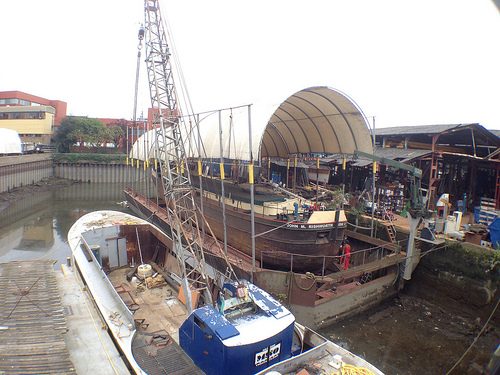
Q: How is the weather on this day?
A: It is cloudy.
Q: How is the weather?
A: It is cloudy.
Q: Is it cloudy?
A: Yes, it is cloudy.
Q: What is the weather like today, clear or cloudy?
A: It is cloudy.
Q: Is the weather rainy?
A: No, it is cloudy.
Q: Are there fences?
A: No, there are no fences.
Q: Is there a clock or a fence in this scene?
A: No, there are no fences or clocks.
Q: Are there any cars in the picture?
A: No, there are no cars.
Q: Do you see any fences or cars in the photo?
A: No, there are no cars or fences.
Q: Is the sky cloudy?
A: Yes, the sky is cloudy.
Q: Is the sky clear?
A: No, the sky is cloudy.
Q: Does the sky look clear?
A: No, the sky is cloudy.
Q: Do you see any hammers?
A: No, there are no hammers.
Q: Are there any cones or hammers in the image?
A: No, there are no hammers or cones.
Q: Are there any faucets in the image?
A: No, there are no faucets.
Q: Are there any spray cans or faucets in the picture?
A: No, there are no faucets or spray cans.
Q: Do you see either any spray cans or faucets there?
A: No, there are no faucets or spray cans.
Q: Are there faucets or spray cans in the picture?
A: No, there are no faucets or spray cans.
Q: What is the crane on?
A: The crane is on the boat.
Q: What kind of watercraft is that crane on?
A: The crane is on the boat.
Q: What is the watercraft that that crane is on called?
A: The watercraft is a boat.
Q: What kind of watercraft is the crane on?
A: The crane is on the boat.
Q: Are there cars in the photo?
A: No, there are no cars.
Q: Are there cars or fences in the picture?
A: No, there are no cars or fences.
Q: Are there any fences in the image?
A: No, there are no fences.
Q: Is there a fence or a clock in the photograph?
A: No, there are no fences or clocks.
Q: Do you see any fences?
A: No, there are no fences.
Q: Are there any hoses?
A: No, there are no hoses.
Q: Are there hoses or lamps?
A: No, there are no hoses or lamps.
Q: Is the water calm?
A: Yes, the water is calm.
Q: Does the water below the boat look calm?
A: Yes, the water is calm.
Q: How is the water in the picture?
A: The water is calm.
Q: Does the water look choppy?
A: No, the water is calm.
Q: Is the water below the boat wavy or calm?
A: The water is calm.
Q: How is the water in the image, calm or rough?
A: The water is calm.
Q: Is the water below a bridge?
A: No, the water is below the boat.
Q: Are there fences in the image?
A: No, there are no fences.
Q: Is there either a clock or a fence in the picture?
A: No, there are no fences or clocks.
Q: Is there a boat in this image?
A: Yes, there is a boat.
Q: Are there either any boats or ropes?
A: Yes, there is a boat.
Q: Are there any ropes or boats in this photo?
A: Yes, there is a boat.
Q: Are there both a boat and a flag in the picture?
A: No, there is a boat but no flags.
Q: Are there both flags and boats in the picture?
A: No, there is a boat but no flags.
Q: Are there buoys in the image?
A: No, there are no buoys.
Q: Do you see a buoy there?
A: No, there are no buoys.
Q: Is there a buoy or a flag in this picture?
A: No, there are no buoys or flags.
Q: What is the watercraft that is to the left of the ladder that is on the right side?
A: The watercraft is a boat.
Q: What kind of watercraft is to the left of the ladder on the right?
A: The watercraft is a boat.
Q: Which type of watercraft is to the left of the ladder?
A: The watercraft is a boat.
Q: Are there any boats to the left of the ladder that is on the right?
A: Yes, there is a boat to the left of the ladder.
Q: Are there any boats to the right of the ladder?
A: No, the boat is to the left of the ladder.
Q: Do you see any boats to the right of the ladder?
A: No, the boat is to the left of the ladder.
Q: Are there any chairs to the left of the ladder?
A: No, there is a boat to the left of the ladder.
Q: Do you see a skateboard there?
A: No, there are no skateboards.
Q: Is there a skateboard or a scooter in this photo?
A: No, there are no skateboards or scooters.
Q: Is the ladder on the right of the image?
A: Yes, the ladder is on the right of the image.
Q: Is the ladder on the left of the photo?
A: No, the ladder is on the right of the image.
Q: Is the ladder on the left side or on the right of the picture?
A: The ladder is on the right of the image.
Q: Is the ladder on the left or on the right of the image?
A: The ladder is on the right of the image.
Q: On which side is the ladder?
A: The ladder is on the right of the image.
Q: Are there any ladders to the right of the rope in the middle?
A: Yes, there is a ladder to the right of the rope.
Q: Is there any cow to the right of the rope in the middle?
A: No, there is a ladder to the right of the rope.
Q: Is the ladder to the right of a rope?
A: Yes, the ladder is to the right of a rope.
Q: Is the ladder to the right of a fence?
A: No, the ladder is to the right of a rope.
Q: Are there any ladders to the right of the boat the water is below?
A: Yes, there is a ladder to the right of the boat.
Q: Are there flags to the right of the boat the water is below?
A: No, there is a ladder to the right of the boat.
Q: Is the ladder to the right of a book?
A: No, the ladder is to the right of a boat.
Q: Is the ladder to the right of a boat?
A: Yes, the ladder is to the right of a boat.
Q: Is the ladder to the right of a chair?
A: No, the ladder is to the right of a boat.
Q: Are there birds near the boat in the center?
A: No, there is a ladder near the boat.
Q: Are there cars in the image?
A: No, there are no cars.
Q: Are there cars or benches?
A: No, there are no cars or benches.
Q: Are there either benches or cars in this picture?
A: No, there are no cars or benches.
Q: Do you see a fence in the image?
A: No, there are no fences.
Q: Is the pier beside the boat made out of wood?
A: Yes, the dock is made of wood.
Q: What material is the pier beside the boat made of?
A: The pier is made of wood.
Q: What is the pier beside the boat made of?
A: The pier is made of wood.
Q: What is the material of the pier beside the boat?
A: The pier is made of wood.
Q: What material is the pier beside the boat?
A: The pier is made of wood.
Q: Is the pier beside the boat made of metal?
A: No, the pier is made of wood.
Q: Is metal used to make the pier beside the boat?
A: No, the pier is made of wood.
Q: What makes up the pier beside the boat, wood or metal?
A: The dock is made of wood.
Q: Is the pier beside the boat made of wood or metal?
A: The dock is made of wood.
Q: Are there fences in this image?
A: No, there are no fences.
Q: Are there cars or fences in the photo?
A: No, there are no fences or cars.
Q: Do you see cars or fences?
A: No, there are no fences or cars.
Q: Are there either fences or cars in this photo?
A: No, there are no fences or cars.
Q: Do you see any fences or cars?
A: No, there are no fences or cars.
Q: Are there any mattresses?
A: No, there are no mattresses.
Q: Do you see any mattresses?
A: No, there are no mattresses.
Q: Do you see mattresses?
A: No, there are no mattresses.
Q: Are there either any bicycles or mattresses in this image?
A: No, there are no mattresses or bicycles.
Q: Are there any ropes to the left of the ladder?
A: Yes, there is a rope to the left of the ladder.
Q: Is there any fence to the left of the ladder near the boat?
A: No, there is a rope to the left of the ladder.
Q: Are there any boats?
A: Yes, there is a boat.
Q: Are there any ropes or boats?
A: Yes, there is a boat.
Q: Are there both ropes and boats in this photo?
A: Yes, there are both a boat and a rope.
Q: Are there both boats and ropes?
A: Yes, there are both a boat and a rope.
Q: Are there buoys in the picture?
A: No, there are no buoys.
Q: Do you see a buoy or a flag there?
A: No, there are no buoys or flags.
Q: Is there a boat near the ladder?
A: Yes, there is a boat near the ladder.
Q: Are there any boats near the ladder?
A: Yes, there is a boat near the ladder.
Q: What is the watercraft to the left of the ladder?
A: The watercraft is a boat.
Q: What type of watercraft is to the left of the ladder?
A: The watercraft is a boat.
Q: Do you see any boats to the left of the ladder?
A: Yes, there is a boat to the left of the ladder.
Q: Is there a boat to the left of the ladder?
A: Yes, there is a boat to the left of the ladder.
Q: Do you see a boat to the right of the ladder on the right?
A: No, the boat is to the left of the ladder.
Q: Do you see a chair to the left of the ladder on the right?
A: No, there is a boat to the left of the ladder.